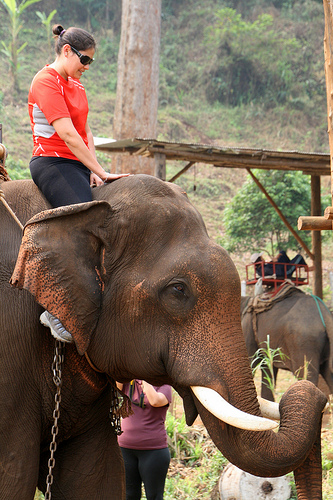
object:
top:
[23, 9, 96, 129]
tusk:
[185, 378, 281, 442]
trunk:
[167, 371, 332, 479]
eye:
[165, 271, 192, 301]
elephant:
[0, 174, 262, 494]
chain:
[46, 333, 65, 491]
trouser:
[26, 146, 99, 212]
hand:
[68, 144, 104, 170]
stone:
[215, 456, 294, 500]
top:
[115, 384, 172, 455]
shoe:
[35, 303, 78, 346]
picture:
[0, 0, 332, 499]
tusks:
[190, 382, 279, 434]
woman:
[20, 15, 109, 211]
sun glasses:
[67, 43, 99, 72]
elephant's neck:
[35, 174, 120, 443]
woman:
[118, 372, 172, 499]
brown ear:
[9, 199, 114, 357]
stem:
[111, 0, 161, 184]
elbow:
[148, 385, 164, 411]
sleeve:
[159, 382, 175, 405]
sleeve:
[30, 71, 72, 126]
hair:
[52, 22, 96, 55]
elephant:
[234, 244, 333, 396]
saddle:
[239, 243, 314, 298]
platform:
[88, 132, 333, 183]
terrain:
[85, 6, 330, 163]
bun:
[46, 19, 78, 44]